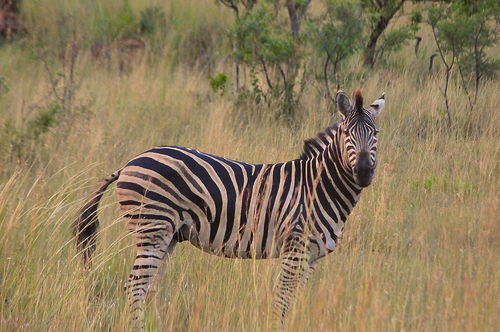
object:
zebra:
[71, 88, 391, 331]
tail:
[70, 164, 126, 269]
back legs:
[121, 236, 171, 332]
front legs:
[266, 255, 307, 332]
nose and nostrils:
[351, 162, 372, 177]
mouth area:
[346, 167, 377, 188]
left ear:
[369, 93, 387, 119]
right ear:
[333, 89, 353, 118]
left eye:
[370, 129, 380, 140]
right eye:
[342, 127, 350, 138]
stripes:
[143, 148, 223, 248]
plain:
[0, 0, 499, 331]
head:
[327, 89, 387, 189]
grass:
[0, 0, 499, 331]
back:
[0, 1, 72, 282]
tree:
[354, 0, 414, 69]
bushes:
[0, 0, 499, 125]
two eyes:
[339, 127, 382, 137]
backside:
[133, 135, 338, 182]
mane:
[298, 122, 342, 160]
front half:
[240, 90, 387, 331]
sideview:
[333, 107, 365, 187]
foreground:
[0, 79, 498, 331]